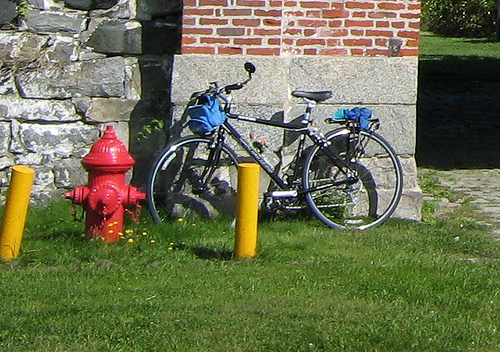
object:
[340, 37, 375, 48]
brick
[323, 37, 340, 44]
brick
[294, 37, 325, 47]
brick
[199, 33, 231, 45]
brick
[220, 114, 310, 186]
black frame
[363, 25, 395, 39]
brick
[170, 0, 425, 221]
wall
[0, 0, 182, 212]
wall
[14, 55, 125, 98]
rocks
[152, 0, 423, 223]
building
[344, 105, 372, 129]
blue item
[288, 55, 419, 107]
blocks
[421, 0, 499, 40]
green shrubs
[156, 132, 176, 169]
reflector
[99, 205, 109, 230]
chain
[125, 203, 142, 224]
chain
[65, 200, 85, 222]
chain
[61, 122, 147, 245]
fire hydrant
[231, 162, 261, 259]
pole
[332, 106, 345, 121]
cloth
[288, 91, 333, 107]
seat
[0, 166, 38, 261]
post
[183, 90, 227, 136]
bag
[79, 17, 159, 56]
stones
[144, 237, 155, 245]
flowers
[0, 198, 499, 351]
grass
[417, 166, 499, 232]
driveway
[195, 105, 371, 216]
frame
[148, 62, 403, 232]
bicycle